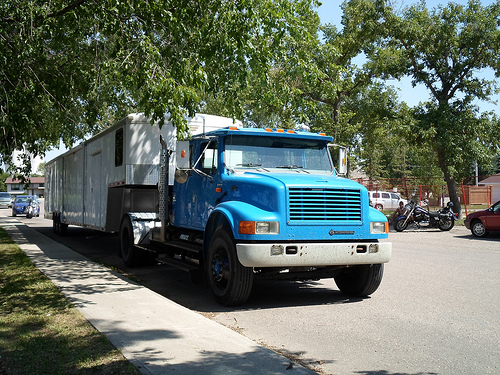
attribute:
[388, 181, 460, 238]
motorcycle — parked sideways, black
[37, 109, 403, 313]
truck — large, cab+trailer, parked, vehicle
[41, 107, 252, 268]
trailer — large, enclosed, white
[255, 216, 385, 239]
headlights — off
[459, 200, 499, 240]
car — red, front only, driver side only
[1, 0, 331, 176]
leaves — weepy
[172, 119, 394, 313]
cab — blue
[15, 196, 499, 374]
street — asphalt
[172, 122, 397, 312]
truck cab — wide, unoccupied, sky blue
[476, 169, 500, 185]
roof — brown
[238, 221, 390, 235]
turn signals — orange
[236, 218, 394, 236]
signal lights — orange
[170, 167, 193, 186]
attached mirror — small, round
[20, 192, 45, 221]
motorcycle — police motorcycle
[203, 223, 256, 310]
tire — large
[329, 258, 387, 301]
tire — large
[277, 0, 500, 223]
trees — overlapping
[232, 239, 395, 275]
bumper — front bumper, white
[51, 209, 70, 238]
back wheels — three, very close together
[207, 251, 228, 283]
hubcap — blue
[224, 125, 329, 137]
clearance lights — orange